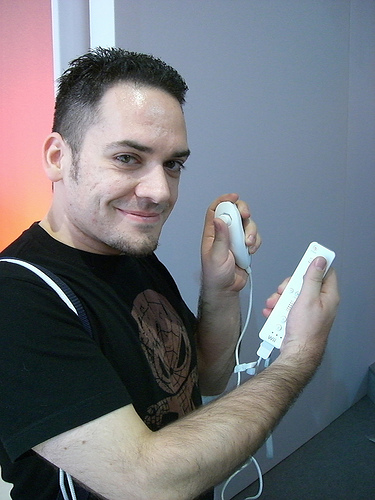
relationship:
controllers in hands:
[211, 199, 252, 271] [198, 191, 262, 295]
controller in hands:
[256, 237, 335, 360] [260, 256, 342, 368]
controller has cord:
[256, 237, 335, 360] [235, 267, 264, 371]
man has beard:
[0, 42, 338, 500] [97, 231, 158, 254]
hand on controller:
[200, 190, 261, 289] [258, 241, 337, 353]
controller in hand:
[256, 237, 335, 360] [281, 261, 339, 361]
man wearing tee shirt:
[0, 42, 338, 500] [90, 276, 167, 347]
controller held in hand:
[256, 237, 335, 360] [282, 265, 344, 361]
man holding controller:
[37, 105, 272, 491] [256, 237, 335, 360]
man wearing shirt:
[37, 105, 272, 491] [23, 239, 190, 423]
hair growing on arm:
[157, 431, 231, 445] [164, 357, 324, 496]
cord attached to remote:
[241, 267, 264, 372] [265, 234, 345, 370]